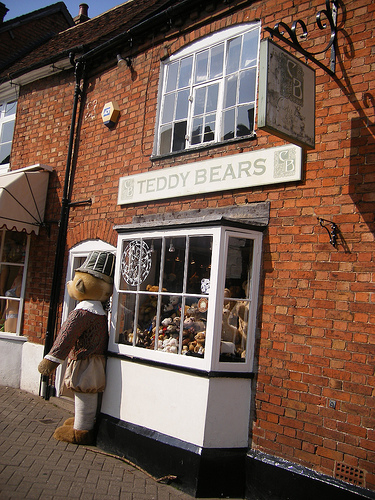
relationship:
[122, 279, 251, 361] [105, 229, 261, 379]
animals fill window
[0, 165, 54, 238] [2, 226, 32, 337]
awning above window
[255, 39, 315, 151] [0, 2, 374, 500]
sign hangs from building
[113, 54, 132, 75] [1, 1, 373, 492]
lamp on wall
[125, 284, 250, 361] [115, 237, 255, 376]
bears on display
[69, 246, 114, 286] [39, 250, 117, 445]
hat on bear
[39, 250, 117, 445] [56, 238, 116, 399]
bear by door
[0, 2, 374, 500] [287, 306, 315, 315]
building with brick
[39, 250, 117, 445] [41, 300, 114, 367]
bear wearing sweater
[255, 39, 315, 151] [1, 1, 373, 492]
sign on wall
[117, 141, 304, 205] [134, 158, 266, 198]
sign reads teddy bears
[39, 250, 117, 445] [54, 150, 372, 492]
bear outside shop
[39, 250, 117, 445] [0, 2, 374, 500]
bear standing outside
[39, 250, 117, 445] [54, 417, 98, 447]
bear has feet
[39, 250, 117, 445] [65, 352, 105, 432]
bear has leg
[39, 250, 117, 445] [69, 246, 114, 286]
bear has hat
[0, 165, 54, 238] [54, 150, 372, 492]
awning next to shop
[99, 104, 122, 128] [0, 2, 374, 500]
sign on building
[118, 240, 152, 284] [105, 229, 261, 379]
design on window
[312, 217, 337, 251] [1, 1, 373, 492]
fixture on wall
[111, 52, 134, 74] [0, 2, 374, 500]
light on building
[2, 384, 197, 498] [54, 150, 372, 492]
ground outside shop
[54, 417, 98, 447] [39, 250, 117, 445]
feet of bear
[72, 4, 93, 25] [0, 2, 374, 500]
chimney on building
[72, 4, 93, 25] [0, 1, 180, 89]
chimney on roof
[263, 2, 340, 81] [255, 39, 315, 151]
scrollwork supports sign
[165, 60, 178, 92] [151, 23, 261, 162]
window pane in window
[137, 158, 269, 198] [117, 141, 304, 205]
word on sign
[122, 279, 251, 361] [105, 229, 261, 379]
animals in window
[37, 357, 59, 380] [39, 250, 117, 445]
paw of bear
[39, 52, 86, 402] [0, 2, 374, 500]
pipe down building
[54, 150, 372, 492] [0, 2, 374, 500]
shop in building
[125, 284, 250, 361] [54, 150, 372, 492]
bears in shop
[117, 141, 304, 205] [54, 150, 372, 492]
sign to shop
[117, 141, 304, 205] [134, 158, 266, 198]
sign says teddy bears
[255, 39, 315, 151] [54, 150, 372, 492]
sign above shop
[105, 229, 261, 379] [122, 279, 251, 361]
window with animals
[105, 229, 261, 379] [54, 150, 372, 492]
window in shop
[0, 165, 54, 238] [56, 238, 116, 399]
awning next door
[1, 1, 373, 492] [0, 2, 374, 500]
wall on building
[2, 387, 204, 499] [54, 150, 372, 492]
sidewalk outside shop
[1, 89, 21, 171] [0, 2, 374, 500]
window in building